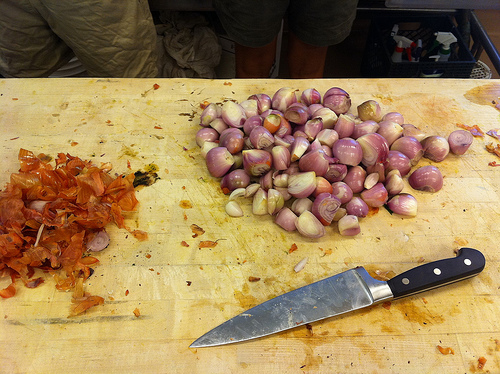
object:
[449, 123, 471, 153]
shallot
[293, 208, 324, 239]
shallot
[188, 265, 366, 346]
edge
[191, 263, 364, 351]
metallic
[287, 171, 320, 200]
onion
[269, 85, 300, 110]
onion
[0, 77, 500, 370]
cutting board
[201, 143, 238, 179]
onions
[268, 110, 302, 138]
shallot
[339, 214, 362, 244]
onion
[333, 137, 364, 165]
shallot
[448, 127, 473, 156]
shallot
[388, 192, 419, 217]
shallot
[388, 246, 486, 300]
handle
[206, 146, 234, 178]
cut shallot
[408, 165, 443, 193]
cut shallot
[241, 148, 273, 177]
cut shallot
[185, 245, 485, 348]
blade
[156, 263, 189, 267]
line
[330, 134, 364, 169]
onion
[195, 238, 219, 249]
small piece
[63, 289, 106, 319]
skins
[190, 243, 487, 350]
knife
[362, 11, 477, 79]
container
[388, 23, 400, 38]
products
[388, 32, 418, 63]
products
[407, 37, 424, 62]
products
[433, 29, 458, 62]
products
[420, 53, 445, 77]
products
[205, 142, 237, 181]
piece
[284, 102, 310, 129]
piece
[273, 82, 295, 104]
shallot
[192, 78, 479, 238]
pile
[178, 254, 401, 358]
area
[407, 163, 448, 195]
onion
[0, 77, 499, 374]
board